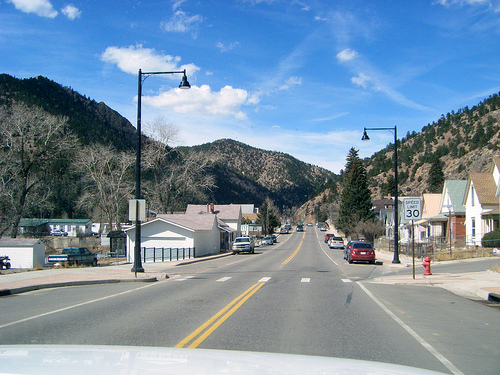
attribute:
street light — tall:
[132, 70, 192, 273]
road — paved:
[0, 226, 499, 374]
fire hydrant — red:
[421, 256, 432, 276]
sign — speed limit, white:
[403, 198, 422, 221]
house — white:
[122, 212, 220, 260]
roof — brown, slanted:
[122, 215, 217, 232]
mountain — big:
[2, 74, 293, 227]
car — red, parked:
[346, 243, 376, 266]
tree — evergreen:
[426, 157, 446, 190]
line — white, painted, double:
[175, 276, 272, 347]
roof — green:
[17, 218, 91, 227]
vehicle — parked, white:
[232, 236, 255, 255]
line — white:
[299, 276, 312, 283]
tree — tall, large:
[336, 146, 378, 239]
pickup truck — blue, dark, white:
[47, 245, 98, 267]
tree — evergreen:
[474, 120, 487, 148]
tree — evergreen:
[320, 193, 329, 206]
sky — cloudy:
[1, 2, 497, 176]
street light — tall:
[362, 126, 401, 262]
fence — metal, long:
[137, 247, 196, 262]